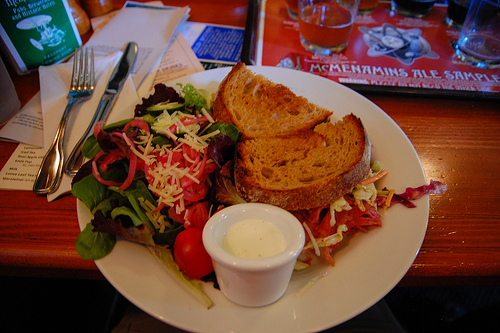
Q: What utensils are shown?
A: Fork and butter knife.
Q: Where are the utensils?
A: Left of plate.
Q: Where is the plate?
A: On table.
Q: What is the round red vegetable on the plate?
A: Tomato.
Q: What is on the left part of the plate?
A: Salad.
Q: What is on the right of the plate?
A: Sandwich.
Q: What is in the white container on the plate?
A: Dressing.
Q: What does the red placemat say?
A: Mcmenamins ale sample.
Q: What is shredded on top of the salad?
A: Cheese.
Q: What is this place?
A: Restaurant.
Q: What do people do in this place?
A: Eat food.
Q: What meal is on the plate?
A: Sandwich.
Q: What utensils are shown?
A: Fork and knife.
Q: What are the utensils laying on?
A: Napkin.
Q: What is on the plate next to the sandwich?
A: Salad.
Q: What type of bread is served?
A: Toasted.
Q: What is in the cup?
A: Sauce.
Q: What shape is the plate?
A: Circle.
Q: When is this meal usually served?
A: Lunch.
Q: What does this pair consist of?
A: A knife and fork.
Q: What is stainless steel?
A: Fork.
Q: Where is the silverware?
A: On top of a napkin.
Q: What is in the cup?
A: Ranch dressing.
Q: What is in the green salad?
A: Vegetables.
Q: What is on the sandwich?
A: Grilled meat and cheese.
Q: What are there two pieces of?
A: Toasted bread.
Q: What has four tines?
A: Fork.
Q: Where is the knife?
A: Next to the fork.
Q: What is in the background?
A: Menu.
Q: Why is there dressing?
A: For salad.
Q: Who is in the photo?
A: No one.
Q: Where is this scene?
A: Restaurant.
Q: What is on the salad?
A: Cheese.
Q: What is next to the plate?
A: Silverware.